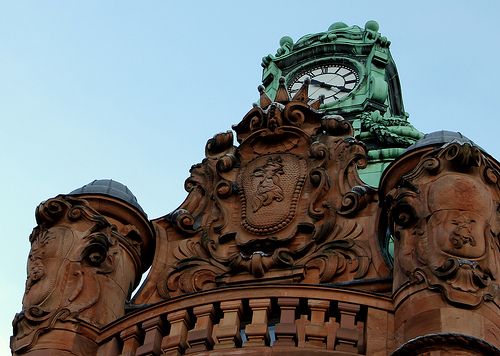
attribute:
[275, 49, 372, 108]
numerals — roman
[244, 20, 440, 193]
structure — green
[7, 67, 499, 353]
structure — brown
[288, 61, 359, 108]
hands — black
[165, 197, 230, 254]
curl — red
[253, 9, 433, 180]
clock — large, green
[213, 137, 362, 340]
stonework — ornate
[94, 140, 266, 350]
section — bronze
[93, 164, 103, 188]
domes — black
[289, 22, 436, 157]
section — petina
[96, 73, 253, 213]
sky — blue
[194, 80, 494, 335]
stonework — renaissance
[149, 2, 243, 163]
sky — blue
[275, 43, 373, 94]
tower — green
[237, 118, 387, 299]
building — brown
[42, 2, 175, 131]
sky — clear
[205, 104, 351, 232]
sculptures — brown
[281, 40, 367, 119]
clock — white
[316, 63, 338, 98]
hands — black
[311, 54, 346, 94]
numbers — black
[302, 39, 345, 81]
numbers — black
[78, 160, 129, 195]
roof — black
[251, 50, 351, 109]
face — white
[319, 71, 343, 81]
number — black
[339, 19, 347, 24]
ball — green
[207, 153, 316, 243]
insignia — regal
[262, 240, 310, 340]
columns — red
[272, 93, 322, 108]
crown — red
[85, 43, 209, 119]
sky — blue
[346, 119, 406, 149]
clock — green